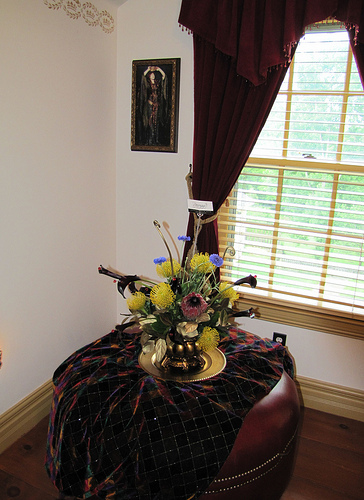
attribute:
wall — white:
[0, 0, 361, 397]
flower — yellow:
[148, 284, 181, 311]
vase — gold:
[158, 320, 211, 373]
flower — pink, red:
[178, 292, 206, 317]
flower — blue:
[209, 251, 225, 271]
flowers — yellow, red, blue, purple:
[122, 259, 246, 326]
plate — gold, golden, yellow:
[136, 340, 225, 383]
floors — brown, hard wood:
[0, 403, 363, 499]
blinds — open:
[211, 24, 362, 313]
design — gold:
[39, 0, 120, 36]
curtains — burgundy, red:
[180, 2, 363, 297]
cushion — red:
[45, 326, 304, 499]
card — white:
[188, 197, 214, 213]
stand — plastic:
[175, 195, 220, 277]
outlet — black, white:
[270, 331, 288, 346]